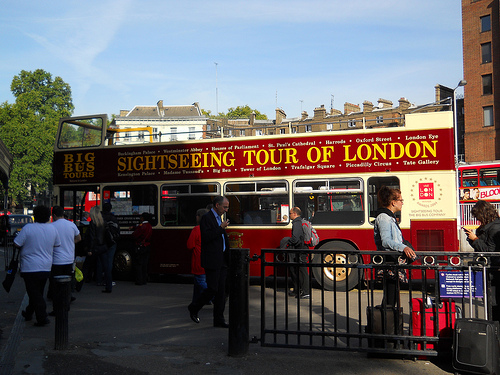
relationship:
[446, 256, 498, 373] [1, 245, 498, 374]
suitcase on ground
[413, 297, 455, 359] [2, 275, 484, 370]
bag on ground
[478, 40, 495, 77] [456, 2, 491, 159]
window on building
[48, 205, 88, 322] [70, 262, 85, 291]
man with hat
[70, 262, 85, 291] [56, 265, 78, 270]
hat hanging from loop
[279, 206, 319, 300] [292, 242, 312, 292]
man wearing pants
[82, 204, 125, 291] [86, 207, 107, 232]
woman with blond hair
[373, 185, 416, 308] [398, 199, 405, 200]
woman has glasses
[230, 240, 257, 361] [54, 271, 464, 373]
black pole on ground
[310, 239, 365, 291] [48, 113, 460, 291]
tire on bus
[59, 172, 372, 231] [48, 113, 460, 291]
window on bus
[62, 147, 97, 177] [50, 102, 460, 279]
print on bus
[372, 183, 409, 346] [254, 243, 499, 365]
woman grasping baracade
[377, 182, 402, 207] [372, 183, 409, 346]
hair on woman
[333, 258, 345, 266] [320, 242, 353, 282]
rust on hubcap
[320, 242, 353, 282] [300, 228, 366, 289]
hubcap on tire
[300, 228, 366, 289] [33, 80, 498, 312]
tire on bus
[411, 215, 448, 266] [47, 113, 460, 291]
vent on bus